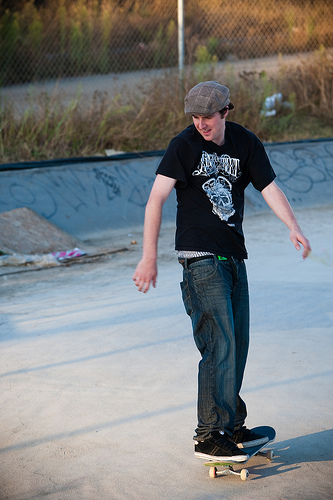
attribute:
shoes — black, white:
[192, 410, 262, 462]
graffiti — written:
[6, 145, 330, 222]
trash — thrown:
[257, 89, 290, 122]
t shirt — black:
[152, 134, 268, 260]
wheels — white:
[206, 448, 277, 487]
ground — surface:
[5, 202, 332, 497]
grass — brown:
[1, 43, 325, 155]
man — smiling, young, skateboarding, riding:
[130, 74, 313, 462]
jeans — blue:
[175, 246, 258, 437]